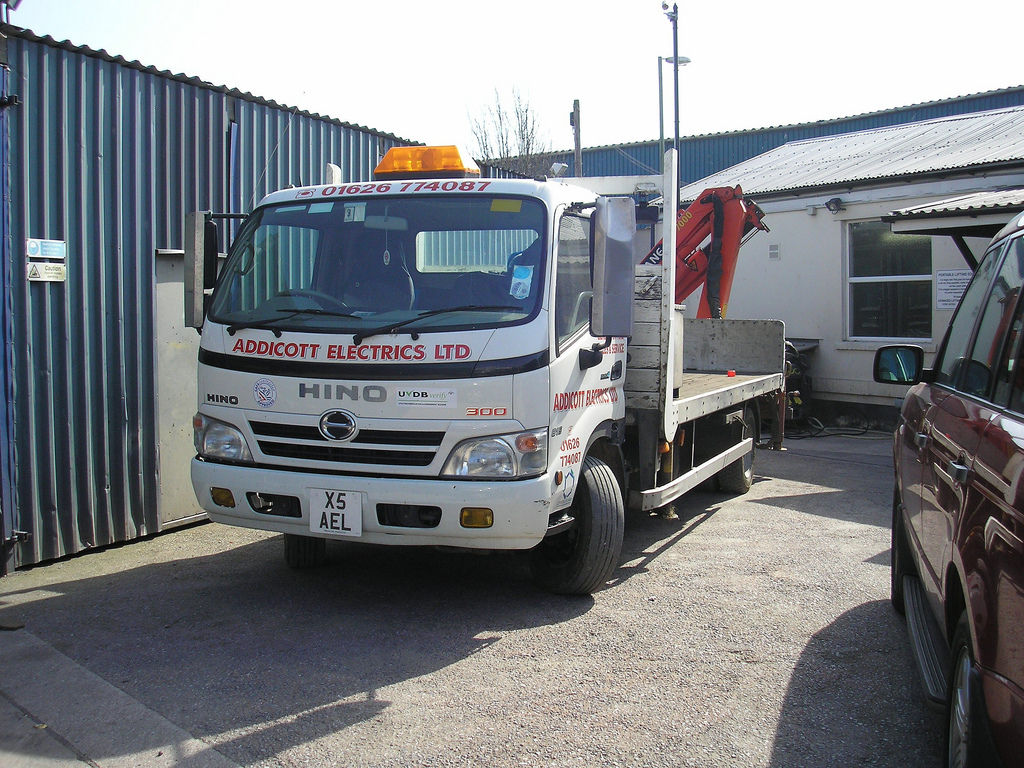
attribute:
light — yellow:
[370, 137, 489, 177]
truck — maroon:
[863, 206, 1021, 764]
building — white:
[640, 96, 1021, 410]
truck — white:
[182, 141, 790, 595]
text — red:
[229, 336, 471, 363]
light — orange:
[372, 143, 481, 180]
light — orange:
[374, 143, 485, 178]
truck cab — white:
[186, 173, 629, 554]